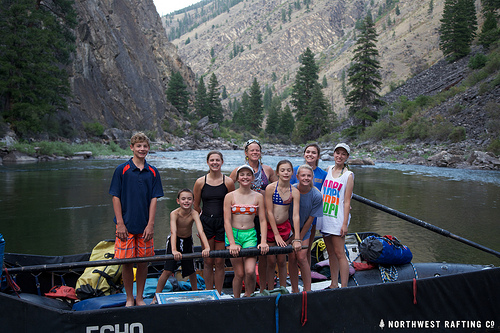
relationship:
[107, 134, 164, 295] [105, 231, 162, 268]
boy wearing shorts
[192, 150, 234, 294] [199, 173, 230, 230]
person wearing shirt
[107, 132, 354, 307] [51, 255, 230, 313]
group on raft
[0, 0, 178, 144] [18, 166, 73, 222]
mountain behind water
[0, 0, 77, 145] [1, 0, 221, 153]
vegetation growing on mountain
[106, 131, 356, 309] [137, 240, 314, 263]
people holding black oar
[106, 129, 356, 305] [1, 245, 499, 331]
people standing on a raft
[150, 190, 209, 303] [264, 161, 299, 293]
boy and girl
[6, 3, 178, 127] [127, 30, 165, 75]
mountain made from stone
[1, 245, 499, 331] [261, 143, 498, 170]
raft near shore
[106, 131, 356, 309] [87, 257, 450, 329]
people on boat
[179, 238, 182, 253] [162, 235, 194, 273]
drawstrings on swim trunks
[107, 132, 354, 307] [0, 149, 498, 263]
group by river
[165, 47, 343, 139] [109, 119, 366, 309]
trees behind people